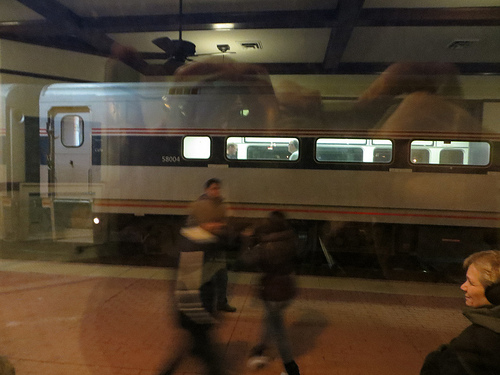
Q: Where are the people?
A: Next to the train.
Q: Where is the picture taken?
A: A train depot.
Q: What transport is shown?
A: Train.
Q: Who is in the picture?
A: Travellers.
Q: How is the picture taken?
A: Through a window.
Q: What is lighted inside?
A: The train.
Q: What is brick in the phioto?
A: Platforn.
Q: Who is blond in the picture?
A: A woman in earmuffs.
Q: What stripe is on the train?
A: An orange one.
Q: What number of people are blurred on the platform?
A: Three.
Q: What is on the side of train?
A: Red stripes.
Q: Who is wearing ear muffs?
A: Lady.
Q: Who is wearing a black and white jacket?
A: A man.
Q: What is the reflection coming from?
A: A train window.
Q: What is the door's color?
A: Silver.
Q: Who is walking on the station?
A: Some people.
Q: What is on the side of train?
A: Windows.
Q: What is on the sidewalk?
A: Red brick.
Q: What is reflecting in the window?
A: An animal.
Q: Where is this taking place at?
A: Train station.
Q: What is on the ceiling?
A: Brown beams.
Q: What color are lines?
A: Red.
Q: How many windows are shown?
A: Four.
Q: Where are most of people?
A: On platform.